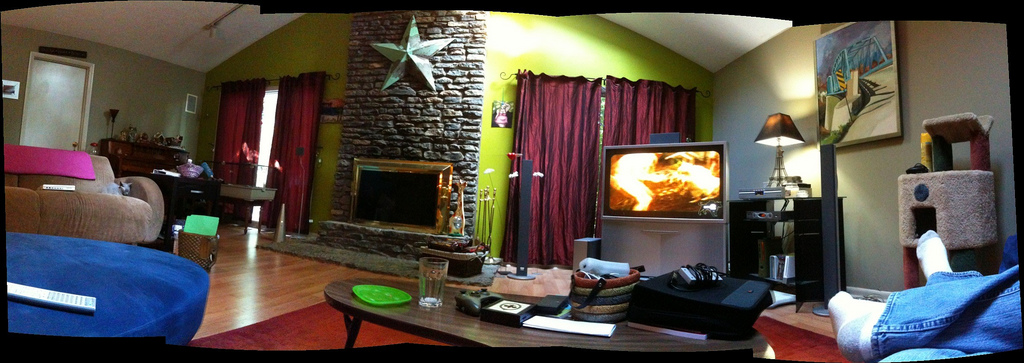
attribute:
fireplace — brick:
[337, 21, 493, 259]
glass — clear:
[414, 255, 451, 303]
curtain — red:
[209, 78, 313, 230]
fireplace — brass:
[343, 147, 469, 236]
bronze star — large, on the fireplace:
[360, 13, 454, 96]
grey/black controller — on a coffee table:
[669, 255, 726, 290]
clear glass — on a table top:
[414, 251, 451, 316]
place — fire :
[335, 139, 478, 239]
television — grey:
[581, 117, 744, 290]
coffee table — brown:
[315, 264, 765, 358]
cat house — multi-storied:
[879, 111, 1018, 302]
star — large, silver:
[361, 13, 468, 107]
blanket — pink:
[2, 136, 113, 201]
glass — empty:
[399, 251, 466, 334]